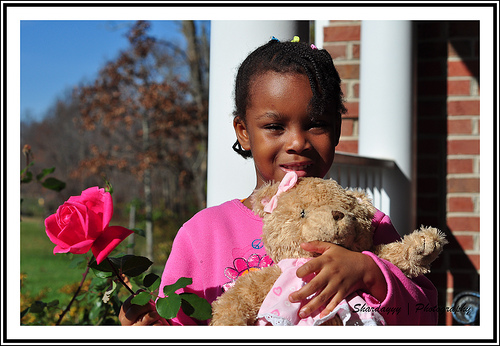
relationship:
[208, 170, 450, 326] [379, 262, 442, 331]
bear in girl's arm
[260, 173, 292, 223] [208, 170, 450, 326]
bow on bear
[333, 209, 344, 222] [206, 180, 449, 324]
nose on teddy bear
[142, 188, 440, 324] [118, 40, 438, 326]
shirt on girl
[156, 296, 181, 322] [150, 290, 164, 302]
leaf on stem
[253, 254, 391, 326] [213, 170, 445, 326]
clothes on bear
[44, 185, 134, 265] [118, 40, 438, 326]
flower next to girl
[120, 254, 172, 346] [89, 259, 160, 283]
leaves next to girl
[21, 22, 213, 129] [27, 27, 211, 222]
sky above trees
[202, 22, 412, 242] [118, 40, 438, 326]
building behind girl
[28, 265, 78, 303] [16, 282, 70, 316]
grass on ground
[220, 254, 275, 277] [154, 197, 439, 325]
design on shirt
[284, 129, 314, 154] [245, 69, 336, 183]
nose on face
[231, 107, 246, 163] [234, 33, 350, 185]
ear on head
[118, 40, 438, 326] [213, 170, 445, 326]
girl holding bear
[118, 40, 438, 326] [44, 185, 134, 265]
girl holding flower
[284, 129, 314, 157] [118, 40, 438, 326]
nose of girl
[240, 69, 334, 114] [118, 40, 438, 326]
forehead of girl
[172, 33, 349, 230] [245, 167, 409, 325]
girl holding bear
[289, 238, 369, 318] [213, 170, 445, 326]
hand in front of bear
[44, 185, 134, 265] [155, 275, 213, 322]
flower on top of leaves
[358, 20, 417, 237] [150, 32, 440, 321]
column behind girl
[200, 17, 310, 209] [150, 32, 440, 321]
column behind girl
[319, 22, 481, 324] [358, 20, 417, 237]
wall behind column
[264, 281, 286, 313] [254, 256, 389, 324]
hearts on fabric